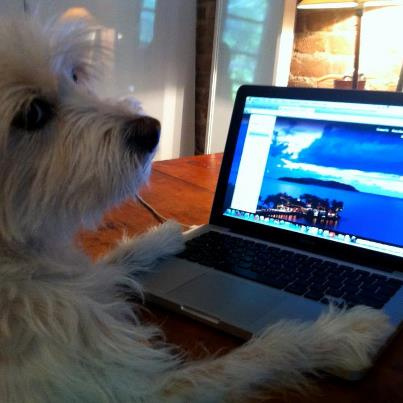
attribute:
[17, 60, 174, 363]
dog — white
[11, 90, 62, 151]
eye — brown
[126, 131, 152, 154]
nostril — black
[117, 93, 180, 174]
nose — black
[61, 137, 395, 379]
table — brown, wooden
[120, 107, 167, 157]
nose — black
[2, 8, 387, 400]
dog — white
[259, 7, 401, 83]
building — brick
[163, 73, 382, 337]
laptop — open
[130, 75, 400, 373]
laptop — black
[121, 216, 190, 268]
paw — white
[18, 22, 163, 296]
dog — white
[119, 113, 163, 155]
nose — black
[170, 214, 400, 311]
keyboard — black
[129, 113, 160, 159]
nose — black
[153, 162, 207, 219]
table — wood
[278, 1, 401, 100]
wall — brick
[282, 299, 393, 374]
dog`s paw — white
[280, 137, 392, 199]
scene — water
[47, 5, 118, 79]
reflection — lamp